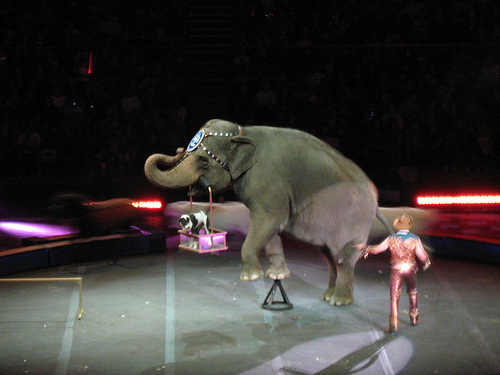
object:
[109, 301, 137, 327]
assortment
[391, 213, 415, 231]
hat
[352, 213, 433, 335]
performer